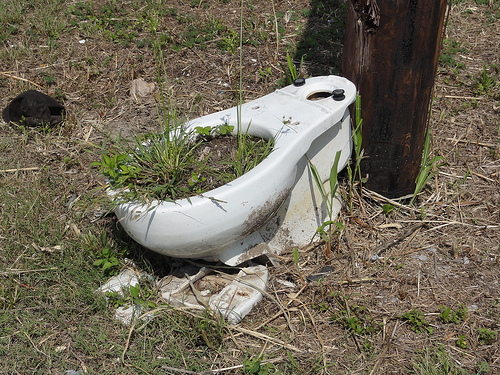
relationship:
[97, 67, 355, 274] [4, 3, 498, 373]
toilet bowl on dirt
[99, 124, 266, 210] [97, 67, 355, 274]
weeds are in toilet bowl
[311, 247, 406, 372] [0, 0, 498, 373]
grass on field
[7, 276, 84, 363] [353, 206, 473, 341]
grass on ground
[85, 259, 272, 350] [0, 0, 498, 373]
trash on field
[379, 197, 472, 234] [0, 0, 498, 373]
hay on field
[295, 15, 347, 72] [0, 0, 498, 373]
shadow casted on field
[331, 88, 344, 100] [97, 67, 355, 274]
screw on toilet bowl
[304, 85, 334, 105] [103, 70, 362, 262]
hole on toilet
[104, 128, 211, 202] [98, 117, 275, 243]
grass in toilet bowl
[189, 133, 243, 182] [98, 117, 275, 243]
dirt in toilet bowl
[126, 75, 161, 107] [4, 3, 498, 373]
rock in dirt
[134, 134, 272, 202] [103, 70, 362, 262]
dirt inside toilet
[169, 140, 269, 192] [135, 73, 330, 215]
grass inside bowl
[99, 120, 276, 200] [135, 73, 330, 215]
weeds inside bowl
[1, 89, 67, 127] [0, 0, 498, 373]
black item on field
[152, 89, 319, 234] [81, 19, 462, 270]
bowl in field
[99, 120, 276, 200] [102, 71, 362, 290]
weeds growing out toilet bowl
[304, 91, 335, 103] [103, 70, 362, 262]
hole in back toilet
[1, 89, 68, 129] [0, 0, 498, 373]
rock on field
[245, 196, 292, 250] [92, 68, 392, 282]
dirt on side toilet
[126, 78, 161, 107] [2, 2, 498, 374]
rock laying in field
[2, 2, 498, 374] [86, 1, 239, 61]
field of grass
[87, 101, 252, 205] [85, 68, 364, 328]
grass growing out toilet bowl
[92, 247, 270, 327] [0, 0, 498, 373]
toilet seat laying on field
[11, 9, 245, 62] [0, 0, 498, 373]
grass growing on field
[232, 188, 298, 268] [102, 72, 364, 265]
dirt on side toilet bowl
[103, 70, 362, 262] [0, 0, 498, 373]
toilet on field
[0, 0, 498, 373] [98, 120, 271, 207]
field with grass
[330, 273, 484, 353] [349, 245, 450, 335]
grass in dirt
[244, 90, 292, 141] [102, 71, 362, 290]
holes in toilet bowl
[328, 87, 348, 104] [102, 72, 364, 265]
screw on toilet bowl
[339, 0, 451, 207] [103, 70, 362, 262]
pole behind toilet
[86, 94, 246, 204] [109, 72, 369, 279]
planter in toilet bowl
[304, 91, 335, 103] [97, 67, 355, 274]
hole in back of toilet bowl